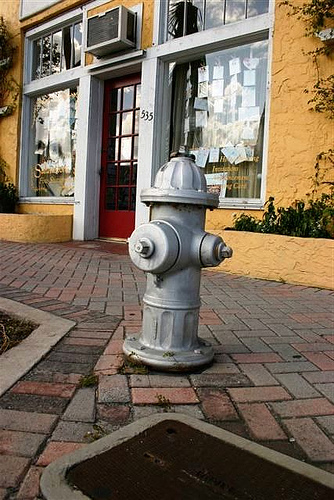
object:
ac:
[83, 4, 139, 61]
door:
[98, 73, 142, 238]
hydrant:
[120, 143, 234, 374]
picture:
[237, 106, 262, 123]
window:
[120, 109, 133, 137]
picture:
[206, 148, 220, 163]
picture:
[197, 66, 209, 98]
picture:
[193, 111, 207, 129]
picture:
[243, 69, 256, 86]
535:
[139, 109, 155, 124]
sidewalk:
[0, 239, 334, 498]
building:
[0, 0, 334, 290]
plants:
[223, 188, 334, 243]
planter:
[200, 229, 334, 291]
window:
[26, 86, 79, 202]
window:
[72, 22, 82, 68]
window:
[245, 0, 268, 20]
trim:
[81, 74, 93, 244]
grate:
[65, 416, 334, 499]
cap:
[127, 220, 179, 274]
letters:
[212, 165, 216, 173]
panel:
[205, 0, 225, 29]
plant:
[0, 183, 20, 214]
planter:
[0, 212, 72, 248]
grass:
[152, 392, 172, 412]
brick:
[281, 416, 334, 462]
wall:
[263, 0, 334, 236]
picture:
[210, 78, 224, 98]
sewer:
[65, 417, 332, 500]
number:
[139, 108, 146, 120]